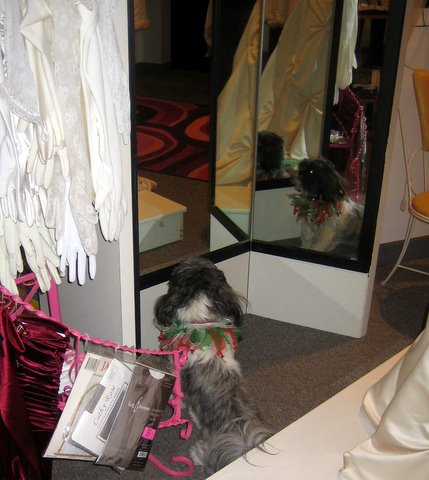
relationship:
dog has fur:
[152, 258, 279, 476] [207, 356, 225, 399]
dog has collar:
[157, 258, 273, 464] [157, 323, 241, 349]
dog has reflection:
[157, 258, 273, 464] [280, 134, 357, 260]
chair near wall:
[407, 69, 425, 337] [368, 37, 423, 253]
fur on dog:
[207, 356, 225, 399] [157, 258, 273, 464]